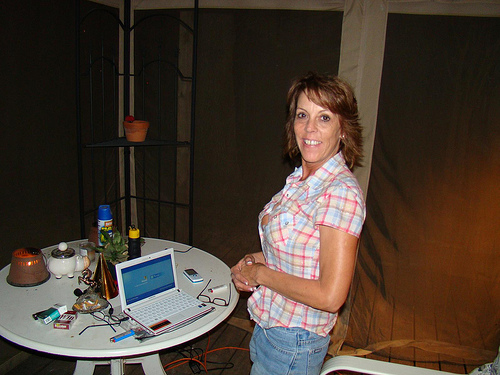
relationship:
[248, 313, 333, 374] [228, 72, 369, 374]
jeans on woman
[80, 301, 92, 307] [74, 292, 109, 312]
butts in ashtray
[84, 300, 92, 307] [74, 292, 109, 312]
butts in ashtray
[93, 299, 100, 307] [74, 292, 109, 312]
butts in ashtray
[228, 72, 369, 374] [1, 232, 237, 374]
woman standing in front of white table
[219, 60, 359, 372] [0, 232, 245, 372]
woman at table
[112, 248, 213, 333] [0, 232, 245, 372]
computer on table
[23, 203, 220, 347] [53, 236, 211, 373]
items on table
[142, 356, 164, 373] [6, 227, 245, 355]
leg of table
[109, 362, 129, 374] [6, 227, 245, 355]
leg of table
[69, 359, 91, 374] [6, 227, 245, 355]
leg of table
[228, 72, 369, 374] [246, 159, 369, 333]
woman wearing shirt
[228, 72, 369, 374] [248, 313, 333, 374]
woman wearing jeans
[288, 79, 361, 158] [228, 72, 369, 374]
hair of woman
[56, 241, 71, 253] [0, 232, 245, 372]
candle on table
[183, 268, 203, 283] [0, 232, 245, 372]
cellphone on table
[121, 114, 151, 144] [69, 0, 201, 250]
clay pot on shelf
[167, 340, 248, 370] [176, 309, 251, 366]
electrical cords on floor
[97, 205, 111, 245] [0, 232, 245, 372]
can on table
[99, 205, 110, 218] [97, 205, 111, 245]
top on can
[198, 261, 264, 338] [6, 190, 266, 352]
glasses on table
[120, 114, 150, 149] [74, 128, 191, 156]
clay pot on shelf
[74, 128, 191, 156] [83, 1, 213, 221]
shelf of stand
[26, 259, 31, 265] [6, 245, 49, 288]
candle in candle holder